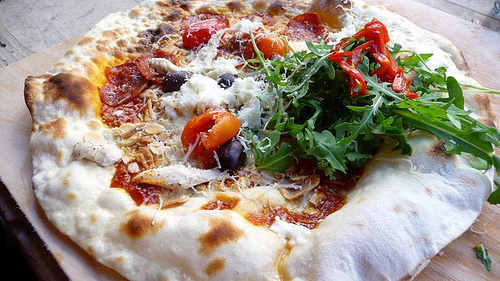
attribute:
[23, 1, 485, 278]
pizza — homemade, cooked, baked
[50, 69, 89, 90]
pizza — burnt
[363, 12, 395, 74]
pepper — red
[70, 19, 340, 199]
cheese — white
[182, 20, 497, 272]
vegetables — green, leafed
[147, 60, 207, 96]
olives — black